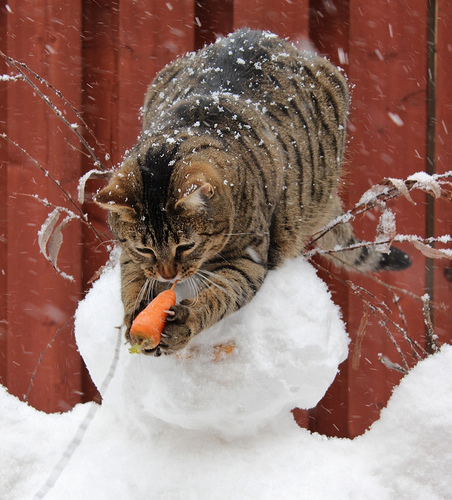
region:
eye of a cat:
[171, 240, 196, 266]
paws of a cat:
[172, 316, 188, 342]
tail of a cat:
[352, 248, 373, 255]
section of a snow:
[386, 419, 404, 449]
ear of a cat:
[196, 187, 216, 205]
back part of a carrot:
[136, 329, 157, 349]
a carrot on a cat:
[150, 319, 155, 326]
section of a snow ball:
[227, 371, 270, 409]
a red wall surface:
[377, 329, 389, 347]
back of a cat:
[223, 52, 249, 113]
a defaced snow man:
[5, 204, 438, 498]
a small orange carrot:
[114, 276, 206, 371]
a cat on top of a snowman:
[52, 5, 402, 400]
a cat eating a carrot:
[41, 97, 329, 399]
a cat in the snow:
[24, 3, 445, 358]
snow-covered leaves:
[345, 154, 448, 316]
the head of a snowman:
[26, 195, 394, 463]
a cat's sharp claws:
[157, 301, 195, 363]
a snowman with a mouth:
[54, 223, 401, 451]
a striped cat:
[81, 6, 436, 383]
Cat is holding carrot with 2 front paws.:
[125, 277, 225, 407]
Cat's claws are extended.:
[130, 312, 199, 369]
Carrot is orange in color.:
[130, 284, 163, 358]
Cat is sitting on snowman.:
[82, 244, 305, 439]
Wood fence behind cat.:
[19, 249, 124, 387]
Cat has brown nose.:
[163, 262, 183, 286]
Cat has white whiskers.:
[166, 263, 260, 310]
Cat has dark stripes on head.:
[140, 191, 196, 265]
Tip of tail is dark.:
[364, 236, 402, 268]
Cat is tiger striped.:
[84, 206, 377, 294]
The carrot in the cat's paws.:
[123, 287, 181, 347]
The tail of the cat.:
[329, 201, 414, 275]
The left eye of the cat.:
[127, 238, 159, 258]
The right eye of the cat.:
[174, 240, 194, 254]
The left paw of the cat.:
[124, 289, 156, 338]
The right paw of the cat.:
[164, 309, 185, 362]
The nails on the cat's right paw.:
[160, 302, 178, 358]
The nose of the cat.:
[156, 266, 178, 279]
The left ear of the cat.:
[94, 182, 139, 227]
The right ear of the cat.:
[176, 178, 217, 217]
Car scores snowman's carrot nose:
[96, 163, 274, 372]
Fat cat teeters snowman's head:
[93, 15, 325, 370]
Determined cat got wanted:
[98, 170, 243, 351]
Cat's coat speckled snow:
[127, 26, 343, 215]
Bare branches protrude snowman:
[6, 55, 112, 284]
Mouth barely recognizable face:
[82, 334, 344, 407]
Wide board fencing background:
[342, 2, 451, 381]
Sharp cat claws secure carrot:
[143, 296, 184, 356]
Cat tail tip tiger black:
[298, 157, 424, 295]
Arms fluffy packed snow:
[1, 367, 448, 498]